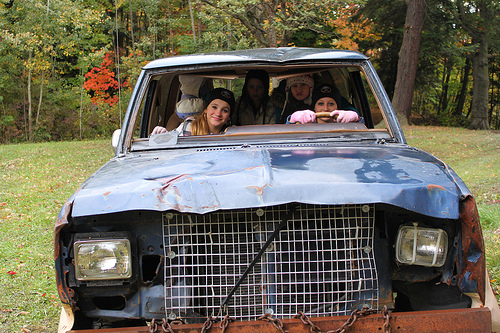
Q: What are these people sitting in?
A: A car.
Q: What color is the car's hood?
A: Blue.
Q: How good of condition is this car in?
A: Not good at all.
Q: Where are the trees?
A: Behind the car.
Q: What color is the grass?
A: Green.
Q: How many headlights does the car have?
A: 2.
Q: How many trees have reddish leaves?
A: 1.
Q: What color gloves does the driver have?
A: Pink.